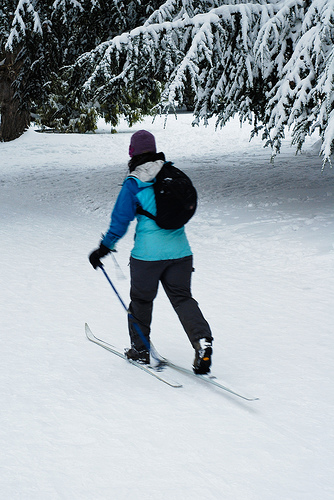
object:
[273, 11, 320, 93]
snow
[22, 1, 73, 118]
tree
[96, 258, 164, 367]
pole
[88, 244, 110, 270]
glove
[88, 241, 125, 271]
hand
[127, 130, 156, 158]
hat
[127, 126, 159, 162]
head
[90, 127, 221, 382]
skier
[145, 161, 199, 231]
backpack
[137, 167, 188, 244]
back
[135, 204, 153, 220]
strap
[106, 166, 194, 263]
coat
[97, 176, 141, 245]
sleeve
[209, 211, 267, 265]
tracks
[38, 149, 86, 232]
snow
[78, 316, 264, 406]
skis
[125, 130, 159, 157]
cap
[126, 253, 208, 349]
pants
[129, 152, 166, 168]
neck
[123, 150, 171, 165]
collar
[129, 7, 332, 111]
branches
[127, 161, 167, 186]
hood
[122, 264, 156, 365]
leg